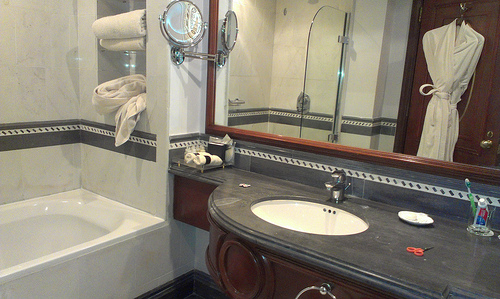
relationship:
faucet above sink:
[322, 168, 352, 203] [231, 193, 373, 247]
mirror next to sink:
[213, 0, 500, 185] [253, 191, 370, 239]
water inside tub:
[3, 206, 115, 273] [1, 182, 182, 297]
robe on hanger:
[415, 17, 484, 162] [403, 59, 481, 200]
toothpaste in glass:
[473, 198, 488, 227] [468, 200, 496, 232]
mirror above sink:
[213, 0, 498, 185] [162, 150, 497, 295]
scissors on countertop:
[405, 244, 434, 256] [167, 148, 499, 297]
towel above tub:
[87, 67, 148, 147] [1, 187, 179, 298]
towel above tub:
[90, 5, 149, 52] [1, 187, 179, 298]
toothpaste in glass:
[473, 198, 490, 229] [469, 205, 495, 236]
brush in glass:
[461, 176, 476, 215] [469, 205, 495, 236]